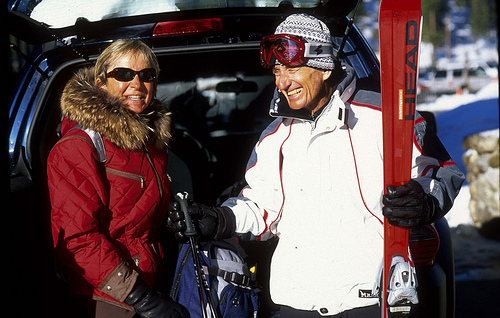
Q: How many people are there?
A: Two.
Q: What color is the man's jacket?
A: White.